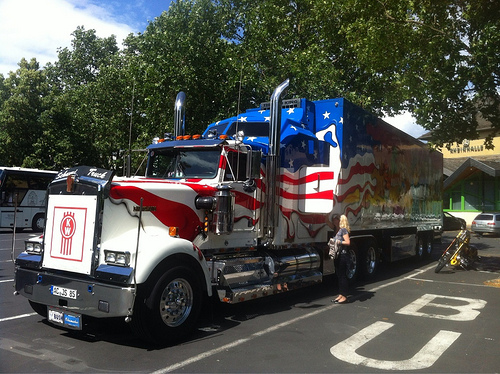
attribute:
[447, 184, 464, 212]
pillars — green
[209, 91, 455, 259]
semi-trailer — painted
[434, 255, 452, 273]
tire — black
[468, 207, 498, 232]
car — gray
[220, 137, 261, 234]
door — closed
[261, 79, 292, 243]
exhaust pipe — silver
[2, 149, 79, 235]
bus — parked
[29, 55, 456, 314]
truck — parked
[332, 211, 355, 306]
woman — blonde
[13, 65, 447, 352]
truck — semi, huge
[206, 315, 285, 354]
line — white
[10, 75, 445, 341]
18 wheeler — truck, american, large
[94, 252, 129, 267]
headlights — off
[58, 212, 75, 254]
logo — red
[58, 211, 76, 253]
kw logo — red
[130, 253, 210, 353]
tire — black, rubber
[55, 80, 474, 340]
truck — semi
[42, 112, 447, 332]
truck — semi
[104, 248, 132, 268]
headlight — off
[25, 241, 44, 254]
headlight — off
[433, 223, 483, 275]
motorcycle — parked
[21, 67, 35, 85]
leaf — green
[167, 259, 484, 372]
cement — painted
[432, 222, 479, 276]
motorcycle — parked